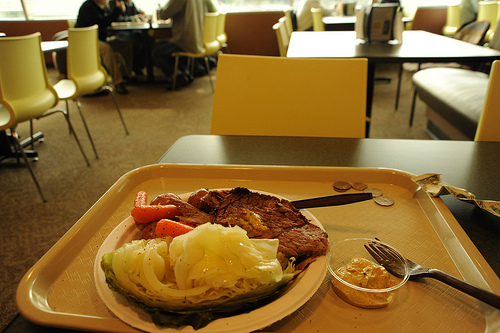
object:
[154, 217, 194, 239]
food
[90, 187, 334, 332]
plate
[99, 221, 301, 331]
cabbage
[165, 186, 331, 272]
corned beef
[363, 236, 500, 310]
fork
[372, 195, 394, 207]
coins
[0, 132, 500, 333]
table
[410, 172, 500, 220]
dollar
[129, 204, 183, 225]
carrots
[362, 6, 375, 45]
holder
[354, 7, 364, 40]
napkin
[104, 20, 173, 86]
table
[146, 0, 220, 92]
people sitting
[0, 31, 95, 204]
chairs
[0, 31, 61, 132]
plastic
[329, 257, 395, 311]
sauce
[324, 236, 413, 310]
plastic cup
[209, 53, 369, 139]
chair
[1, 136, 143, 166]
rug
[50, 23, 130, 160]
chair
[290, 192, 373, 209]
fork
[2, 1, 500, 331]
restaurant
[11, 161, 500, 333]
tray